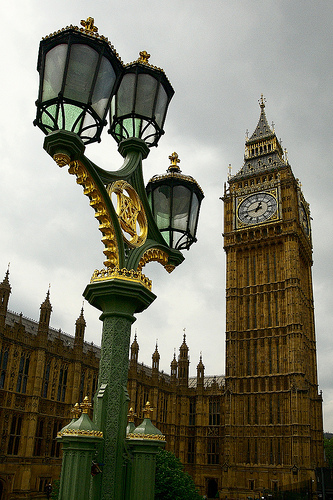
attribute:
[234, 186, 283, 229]
clock — gold, black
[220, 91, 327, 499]
tower — tall, big ben, old, old fashioned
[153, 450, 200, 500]
bush — leafy, green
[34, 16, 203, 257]
lights — three, off, old fashioned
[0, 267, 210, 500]
pillars — tall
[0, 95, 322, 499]
building — brown, old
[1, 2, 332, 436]
sky — overcast, gray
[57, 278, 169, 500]
pole — green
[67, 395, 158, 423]
crosses — gold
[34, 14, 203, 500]
lamp post — ornate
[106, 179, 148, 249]
circle — gold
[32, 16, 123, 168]
lamp — metal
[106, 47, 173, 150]
lamp — metal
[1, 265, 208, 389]
spires — pointy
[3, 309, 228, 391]
roof — grey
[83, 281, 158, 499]
pillar — green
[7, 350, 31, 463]
window — long, tall